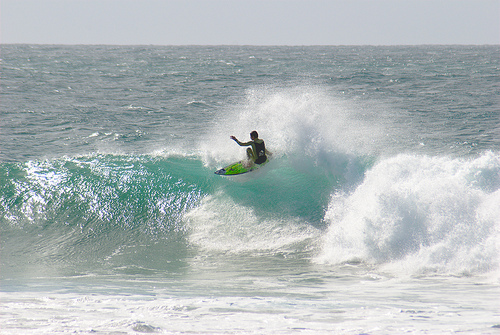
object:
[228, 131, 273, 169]
person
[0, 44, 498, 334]
ocean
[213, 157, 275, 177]
surfboard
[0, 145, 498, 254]
wave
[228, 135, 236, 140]
hand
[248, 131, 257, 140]
hair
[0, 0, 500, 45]
sky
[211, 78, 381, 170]
splash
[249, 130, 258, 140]
head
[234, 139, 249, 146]
arm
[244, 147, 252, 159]
leg